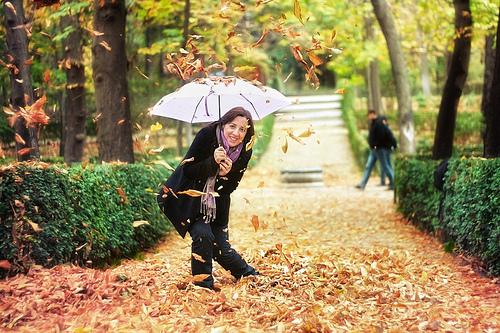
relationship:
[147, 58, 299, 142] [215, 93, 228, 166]
umbrella has handle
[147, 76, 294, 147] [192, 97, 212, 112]
umbrella has spine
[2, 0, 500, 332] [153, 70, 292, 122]
leaves falling over umbrella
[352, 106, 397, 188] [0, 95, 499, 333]
man walking on path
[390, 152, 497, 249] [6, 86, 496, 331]
bushes around path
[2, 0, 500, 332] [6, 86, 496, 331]
leaves on path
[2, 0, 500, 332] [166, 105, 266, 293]
leaves in front of woman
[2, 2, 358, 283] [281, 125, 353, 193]
leaves in air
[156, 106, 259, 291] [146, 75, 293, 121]
man holding umbrella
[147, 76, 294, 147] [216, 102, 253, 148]
umbrella over woman`s head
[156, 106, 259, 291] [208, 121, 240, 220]
man wearing a scarf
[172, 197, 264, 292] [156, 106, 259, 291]
pants on man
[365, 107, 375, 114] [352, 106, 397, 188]
hat on man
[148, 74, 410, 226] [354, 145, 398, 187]
man wearing jeans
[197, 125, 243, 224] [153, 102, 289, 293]
purple scarf around woman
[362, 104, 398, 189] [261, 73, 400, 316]
people walking on path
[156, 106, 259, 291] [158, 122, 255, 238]
man wearing black coat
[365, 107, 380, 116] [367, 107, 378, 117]
brown cap on head